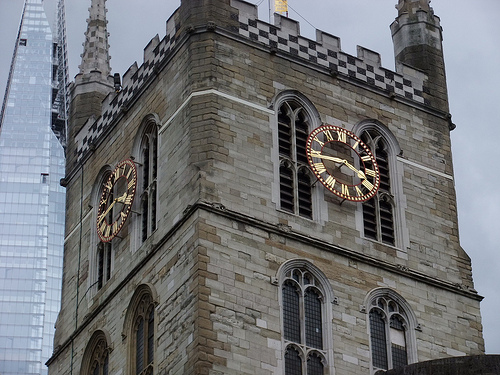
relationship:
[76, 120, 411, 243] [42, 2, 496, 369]
clock on building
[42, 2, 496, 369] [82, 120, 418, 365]
building has windows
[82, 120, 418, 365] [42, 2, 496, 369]
windows on building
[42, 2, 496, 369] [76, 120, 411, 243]
building has clock